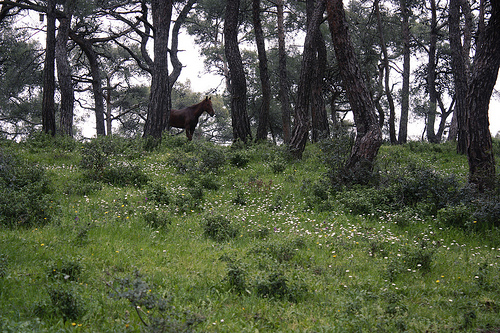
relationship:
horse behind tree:
[166, 94, 216, 142] [108, 1, 197, 148]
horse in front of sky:
[166, 94, 216, 142] [0, 2, 499, 150]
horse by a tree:
[166, 94, 216, 142] [108, 1, 197, 148]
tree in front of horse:
[108, 1, 197, 148] [166, 94, 216, 142]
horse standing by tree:
[166, 94, 216, 142] [108, 1, 197, 148]